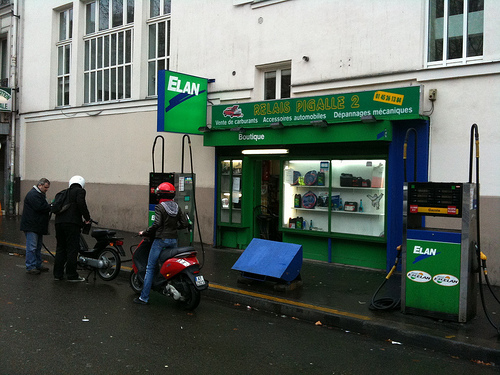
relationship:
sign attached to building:
[156, 77, 204, 134] [148, 5, 392, 61]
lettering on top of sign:
[167, 80, 195, 95] [156, 77, 204, 134]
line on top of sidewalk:
[227, 284, 272, 296] [312, 278, 365, 300]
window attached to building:
[74, 39, 106, 97] [148, 5, 392, 61]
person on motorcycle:
[146, 179, 194, 259] [146, 250, 197, 280]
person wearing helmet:
[146, 179, 194, 259] [147, 176, 177, 193]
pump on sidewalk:
[369, 242, 399, 313] [312, 278, 365, 300]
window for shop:
[74, 39, 106, 97] [237, 147, 381, 252]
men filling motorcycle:
[12, 167, 193, 289] [146, 250, 197, 280]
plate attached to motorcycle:
[197, 269, 209, 286] [146, 250, 197, 280]